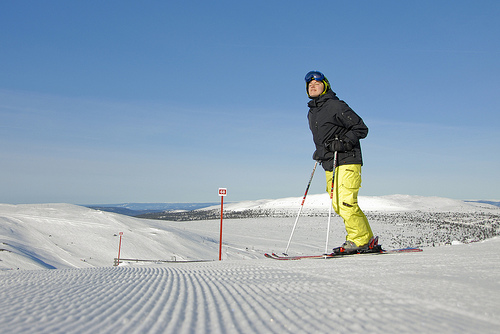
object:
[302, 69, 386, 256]
man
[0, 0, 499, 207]
sky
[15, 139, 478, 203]
clouds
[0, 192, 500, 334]
snow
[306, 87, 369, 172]
jacket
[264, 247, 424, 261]
skis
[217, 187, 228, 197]
sign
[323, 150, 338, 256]
ski pole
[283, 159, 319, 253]
ski pole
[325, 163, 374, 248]
pants